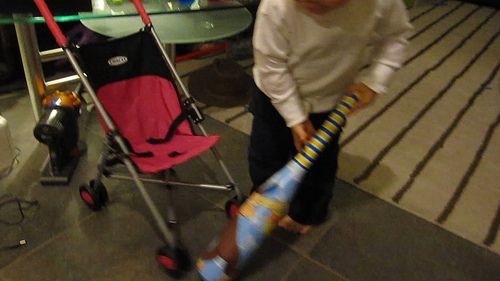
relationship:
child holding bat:
[249, 2, 414, 236] [192, 90, 359, 280]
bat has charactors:
[192, 90, 359, 280] [200, 181, 285, 274]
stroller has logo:
[35, 1, 253, 272] [107, 56, 131, 66]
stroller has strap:
[35, 1, 253, 272] [116, 111, 196, 157]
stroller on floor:
[35, 1, 253, 272] [17, 17, 493, 277]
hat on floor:
[187, 58, 255, 109] [17, 17, 493, 277]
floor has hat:
[17, 17, 493, 277] [187, 58, 255, 109]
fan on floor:
[33, 102, 80, 184] [17, 17, 493, 277]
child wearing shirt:
[249, 2, 414, 236] [252, 0, 413, 140]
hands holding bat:
[288, 82, 377, 155] [192, 90, 359, 280]